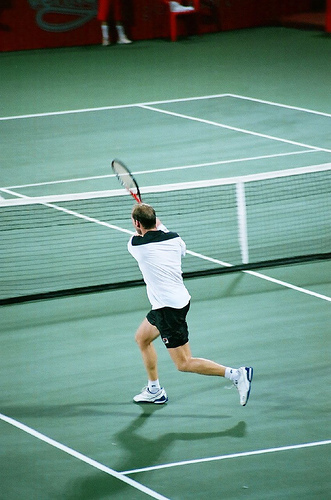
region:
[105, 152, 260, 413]
A man is playing tennis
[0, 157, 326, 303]
A net on the tennis court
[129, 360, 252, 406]
A pair of white sneakers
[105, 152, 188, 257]
A man holding a tennis racket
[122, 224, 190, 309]
A white and black shirt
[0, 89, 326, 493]
White lines on the court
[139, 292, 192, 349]
A pair of black shorts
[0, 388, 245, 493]
Shadows on the tennis court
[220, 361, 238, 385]
A sock is white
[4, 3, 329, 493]
green and white tennis court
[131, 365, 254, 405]
man wearing white tennis shoes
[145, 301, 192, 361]
man wearing black tennis shorts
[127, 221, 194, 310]
man wearing white shirt with black shoulders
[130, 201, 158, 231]
man with short blond hair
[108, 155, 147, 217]
man holding black and red tennis racket above head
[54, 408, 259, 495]
shadow of man on green tennis court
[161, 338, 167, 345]
white logo on black shorts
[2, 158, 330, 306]
tennis net bounded by white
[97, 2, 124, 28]
person wearing red shorts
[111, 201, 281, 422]
THIS IS A PERSON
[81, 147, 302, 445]
the man is playing tennis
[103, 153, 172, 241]
this is a racket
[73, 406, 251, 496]
a shadow of a man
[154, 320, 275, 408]
the foot of a man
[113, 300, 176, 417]
the foot of a man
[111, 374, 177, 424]
this is a sports shoe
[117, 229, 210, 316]
the shirt is white and black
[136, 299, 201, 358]
the shorts are black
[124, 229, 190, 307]
man wearing a white shirt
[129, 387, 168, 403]
man wearing white and blue shoes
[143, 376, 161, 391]
man wearing white socks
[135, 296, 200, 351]
man wearing black shorts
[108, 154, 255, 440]
man holding tennis racket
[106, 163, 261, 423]
man wearing white shirt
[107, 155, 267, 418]
man wearing black shorts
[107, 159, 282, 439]
man wearing white socks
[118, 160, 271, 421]
man wearing white shoes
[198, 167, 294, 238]
net on tennis court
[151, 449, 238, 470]
line on tennis court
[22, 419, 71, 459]
line on tennis court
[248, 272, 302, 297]
line on tennis court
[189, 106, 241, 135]
line on tennis court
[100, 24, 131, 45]
white knee high socks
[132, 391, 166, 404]
a black and white shoe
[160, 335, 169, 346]
white logo on shorts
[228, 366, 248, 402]
a black and white shoe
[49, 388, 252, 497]
a shadow on the court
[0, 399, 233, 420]
a shadow on the court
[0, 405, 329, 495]
white paint on the court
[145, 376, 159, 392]
a black and white sock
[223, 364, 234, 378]
a black and white sock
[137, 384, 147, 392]
a white shoe lace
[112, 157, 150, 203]
The man is holding a tennis racket.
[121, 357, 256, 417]
The man is wearing a pair of white and blue sneakers.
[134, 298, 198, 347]
The man is wearing a pair of black shorts.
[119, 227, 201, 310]
The man is wearing a white and black shirt.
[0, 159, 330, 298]
The tennis net is white and black.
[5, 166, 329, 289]
The tennis net is in the middle of the court.